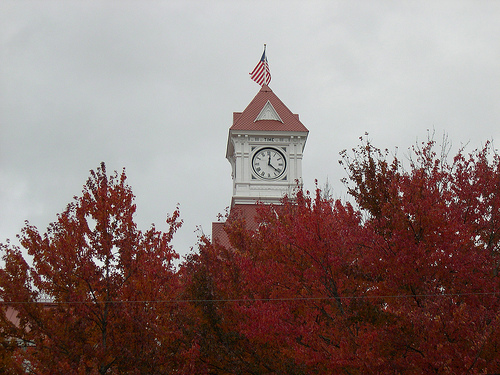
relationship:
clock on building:
[250, 143, 286, 188] [228, 83, 320, 222]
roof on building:
[238, 108, 300, 135] [228, 83, 320, 222]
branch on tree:
[95, 268, 115, 334] [218, 249, 438, 358]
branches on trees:
[89, 281, 117, 351] [56, 194, 494, 359]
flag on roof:
[250, 53, 280, 88] [238, 108, 300, 135]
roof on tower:
[238, 108, 300, 135] [224, 81, 315, 253]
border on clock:
[248, 144, 256, 177] [250, 143, 286, 188]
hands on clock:
[266, 154, 277, 171] [250, 143, 286, 188]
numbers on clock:
[257, 161, 265, 179] [250, 143, 286, 188]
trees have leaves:
[56, 194, 494, 359] [139, 256, 174, 316]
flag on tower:
[250, 53, 280, 88] [224, 81, 315, 253]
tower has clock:
[224, 81, 315, 253] [250, 143, 286, 188]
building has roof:
[228, 83, 320, 222] [238, 108, 300, 135]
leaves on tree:
[139, 256, 174, 316] [218, 249, 438, 358]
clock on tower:
[250, 143, 286, 188] [224, 81, 315, 253]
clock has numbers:
[250, 143, 286, 188] [257, 161, 265, 179]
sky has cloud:
[44, 23, 471, 97] [97, 45, 193, 81]